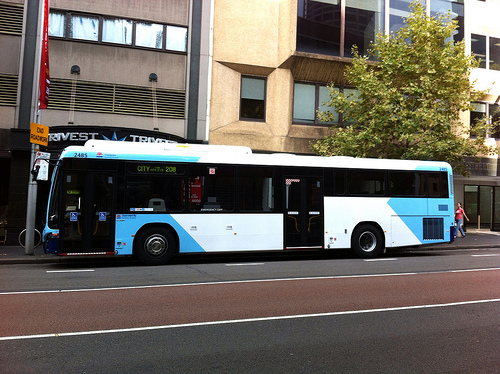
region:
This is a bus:
[15, 118, 477, 291]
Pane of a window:
[42, 0, 72, 44]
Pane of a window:
[64, 9, 104, 45]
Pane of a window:
[98, 17, 138, 47]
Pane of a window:
[134, 13, 164, 45]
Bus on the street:
[38, 135, 468, 269]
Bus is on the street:
[37, 127, 470, 262]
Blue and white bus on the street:
[36, 128, 466, 273]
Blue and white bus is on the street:
[35, 135, 465, 268]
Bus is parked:
[35, 130, 465, 262]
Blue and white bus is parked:
[21, 131, 466, 266]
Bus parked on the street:
[35, 136, 465, 274]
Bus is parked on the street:
[36, 126, 467, 268]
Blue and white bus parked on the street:
[29, 130, 465, 268]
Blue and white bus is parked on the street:
[33, 130, 468, 272]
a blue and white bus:
[61, 137, 451, 244]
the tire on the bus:
[352, 217, 372, 252]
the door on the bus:
[285, 172, 320, 242]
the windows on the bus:
[130, 165, 265, 205]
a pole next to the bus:
[30, 5, 40, 255]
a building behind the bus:
[2, 0, 493, 185]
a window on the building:
[55, 11, 165, 41]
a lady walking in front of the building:
[445, 200, 465, 235]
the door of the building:
[466, 182, 483, 222]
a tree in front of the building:
[325, 15, 480, 151]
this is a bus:
[26, 141, 458, 262]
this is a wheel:
[346, 208, 386, 258]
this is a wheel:
[136, 223, 173, 264]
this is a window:
[38, 4, 67, 34]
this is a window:
[69, 13, 103, 42]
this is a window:
[99, 13, 135, 52]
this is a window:
[129, 20, 161, 45]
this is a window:
[162, 24, 187, 49]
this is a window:
[303, 5, 348, 60]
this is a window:
[346, 5, 376, 64]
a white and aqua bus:
[40, 142, 459, 254]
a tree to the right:
[311, 11, 486, 153]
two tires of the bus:
[134, 222, 381, 256]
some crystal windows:
[51, 8, 184, 55]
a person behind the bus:
[456, 202, 468, 236]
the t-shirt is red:
[456, 207, 462, 218]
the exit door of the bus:
[284, 177, 321, 247]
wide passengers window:
[138, 164, 258, 205]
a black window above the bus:
[240, 75, 265, 122]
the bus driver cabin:
[57, 162, 108, 212]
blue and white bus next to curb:
[41, 137, 456, 259]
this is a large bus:
[56, 79, 464, 319]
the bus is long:
[74, 135, 469, 287]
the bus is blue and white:
[64, 120, 417, 325]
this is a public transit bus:
[41, 139, 408, 341]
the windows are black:
[102, 165, 229, 209]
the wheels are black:
[127, 205, 199, 272]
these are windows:
[86, 13, 164, 40]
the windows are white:
[49, 13, 217, 75]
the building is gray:
[68, 15, 215, 159]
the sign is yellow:
[10, 85, 100, 200]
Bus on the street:
[28, 126, 492, 275]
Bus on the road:
[38, 127, 473, 274]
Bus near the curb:
[31, 135, 465, 268]